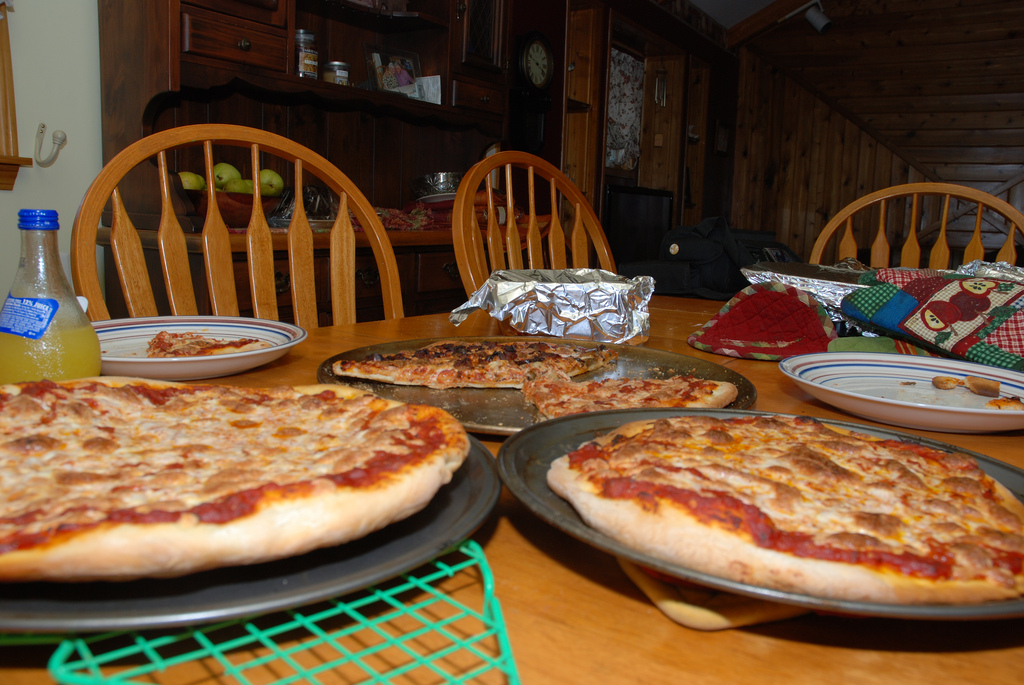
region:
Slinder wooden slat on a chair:
[98, 186, 155, 323]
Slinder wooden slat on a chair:
[146, 148, 198, 320]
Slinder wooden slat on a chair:
[190, 131, 247, 316]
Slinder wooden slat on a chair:
[228, 138, 290, 317]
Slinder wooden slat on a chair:
[276, 145, 319, 317]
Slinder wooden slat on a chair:
[322, 172, 365, 331]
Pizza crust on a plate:
[777, 331, 1022, 446]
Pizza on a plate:
[93, 306, 302, 373]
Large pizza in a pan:
[500, 379, 1016, 635]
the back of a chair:
[59, 120, 385, 305]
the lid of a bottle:
[6, 191, 70, 236]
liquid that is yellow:
[5, 314, 100, 376]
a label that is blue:
[2, 288, 60, 334]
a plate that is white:
[90, 297, 277, 374]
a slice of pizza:
[148, 317, 225, 369]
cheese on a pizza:
[132, 387, 272, 490]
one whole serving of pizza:
[12, 367, 405, 570]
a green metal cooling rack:
[327, 604, 514, 682]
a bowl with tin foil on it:
[493, 260, 640, 336]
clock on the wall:
[514, 31, 553, 93]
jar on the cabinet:
[288, 21, 328, 79]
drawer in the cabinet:
[177, 4, 288, 69]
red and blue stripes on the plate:
[776, 341, 1020, 422]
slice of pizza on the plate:
[137, 309, 268, 366]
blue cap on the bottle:
[11, 202, 57, 235]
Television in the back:
[599, 174, 682, 266]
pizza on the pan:
[1, 364, 477, 593]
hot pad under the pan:
[605, 543, 809, 639]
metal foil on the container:
[741, 255, 903, 355]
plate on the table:
[775, 345, 1022, 445]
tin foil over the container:
[441, 252, 661, 352]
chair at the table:
[437, 142, 616, 298]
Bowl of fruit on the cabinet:
[160, 149, 288, 226]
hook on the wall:
[27, 117, 81, 171]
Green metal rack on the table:
[4, 541, 539, 682]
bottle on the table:
[7, 195, 110, 395]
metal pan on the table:
[317, 325, 771, 433]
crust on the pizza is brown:
[727, 544, 769, 586]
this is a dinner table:
[63, 63, 899, 671]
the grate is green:
[275, 548, 418, 675]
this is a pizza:
[67, 357, 353, 569]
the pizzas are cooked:
[108, 395, 715, 631]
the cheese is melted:
[86, 383, 380, 513]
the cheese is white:
[65, 361, 275, 555]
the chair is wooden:
[111, 136, 419, 299]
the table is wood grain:
[509, 504, 646, 682]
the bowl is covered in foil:
[449, 246, 820, 417]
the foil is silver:
[464, 210, 649, 363]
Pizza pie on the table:
[5, 360, 486, 630]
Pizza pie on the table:
[549, 395, 1020, 639]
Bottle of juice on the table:
[9, 196, 104, 380]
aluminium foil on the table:
[460, 233, 657, 361]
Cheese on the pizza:
[24, 373, 322, 523]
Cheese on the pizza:
[673, 442, 958, 569]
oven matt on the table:
[698, 266, 822, 371]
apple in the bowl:
[196, 148, 235, 186]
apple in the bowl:
[246, 157, 286, 190]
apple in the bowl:
[176, 158, 211, 197]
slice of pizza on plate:
[124, 311, 284, 360]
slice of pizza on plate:
[818, 335, 1021, 419]